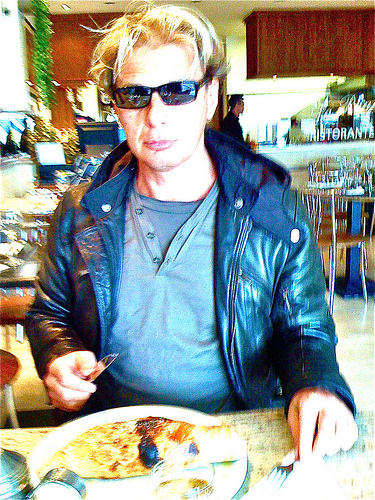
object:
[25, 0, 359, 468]
man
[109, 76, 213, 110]
glasses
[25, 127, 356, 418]
jacket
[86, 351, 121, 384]
knife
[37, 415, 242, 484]
egg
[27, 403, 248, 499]
plate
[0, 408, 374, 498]
table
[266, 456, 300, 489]
fork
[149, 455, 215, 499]
cup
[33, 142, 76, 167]
monitor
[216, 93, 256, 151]
worker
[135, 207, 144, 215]
button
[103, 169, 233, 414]
shirt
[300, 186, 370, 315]
chair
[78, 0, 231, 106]
hair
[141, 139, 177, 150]
lips